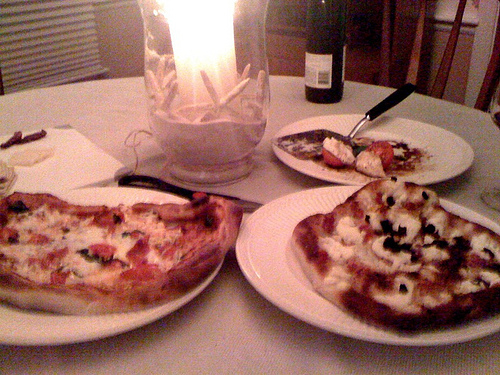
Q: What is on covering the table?
A: Cloth.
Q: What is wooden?
A: A chair.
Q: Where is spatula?
A: Plate.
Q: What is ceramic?
A: Plate.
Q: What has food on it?
A: Plates.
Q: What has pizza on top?
A: Plate.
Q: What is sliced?
A: Pizza.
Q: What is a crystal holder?
A: Candle.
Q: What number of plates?
A: 3.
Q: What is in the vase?
A: A candle.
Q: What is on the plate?
A: A small pizza.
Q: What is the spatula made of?
A: Sliver.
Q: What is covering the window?
A: Blinds.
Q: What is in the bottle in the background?
A: Wine.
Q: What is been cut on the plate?
A: Pizza.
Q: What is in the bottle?
A: Wine.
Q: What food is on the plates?
A: Pizza.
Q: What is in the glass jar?
A: A candle.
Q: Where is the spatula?
A: On the back plate.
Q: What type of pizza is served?
A: Sicilian.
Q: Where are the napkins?
A: Behind the plate on the left.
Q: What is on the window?
A: White blinds.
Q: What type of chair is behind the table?
A: Wooden.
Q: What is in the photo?
A: Food.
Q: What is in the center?
A: Candle.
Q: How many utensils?
A: 2.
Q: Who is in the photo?
A: Noone.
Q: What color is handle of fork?
A: Black.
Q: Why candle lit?
A: Romance.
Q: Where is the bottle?
A: On table.